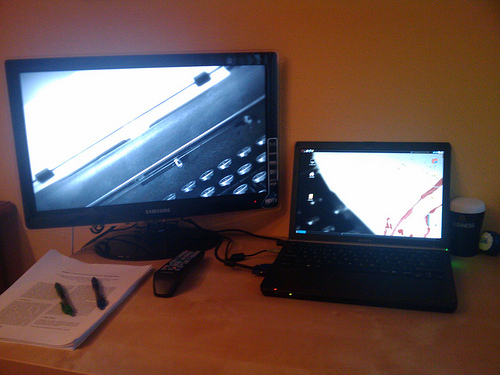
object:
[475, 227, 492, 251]
ball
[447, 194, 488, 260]
beer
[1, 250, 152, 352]
stack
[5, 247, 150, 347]
papers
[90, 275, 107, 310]
pen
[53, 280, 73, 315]
pen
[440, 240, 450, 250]
light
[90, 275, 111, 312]
ink pen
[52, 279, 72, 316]
ink pen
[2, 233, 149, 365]
documents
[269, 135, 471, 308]
laptop monitor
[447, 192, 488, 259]
one cup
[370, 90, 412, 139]
ground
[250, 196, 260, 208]
red light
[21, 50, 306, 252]
monitor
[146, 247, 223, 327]
remote control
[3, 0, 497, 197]
wall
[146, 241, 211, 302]
mouse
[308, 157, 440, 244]
typewriter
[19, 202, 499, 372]
desk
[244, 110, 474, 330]
laptop